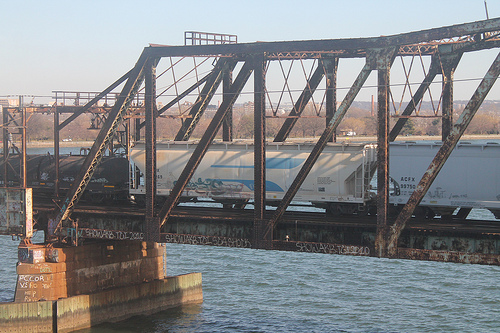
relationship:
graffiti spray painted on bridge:
[170, 218, 252, 238] [3, 13, 498, 269]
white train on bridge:
[277, 151, 377, 194] [31, 62, 498, 264]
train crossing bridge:
[0, 137, 498, 222] [30, 16, 499, 267]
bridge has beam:
[55, 13, 498, 267] [146, 43, 267, 55]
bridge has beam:
[55, 13, 498, 267] [381, 17, 498, 49]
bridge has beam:
[55, 13, 498, 267] [261, 37, 377, 54]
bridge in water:
[30, 16, 499, 267] [0, 232, 500, 330]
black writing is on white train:
[397, 172, 417, 193] [277, 151, 377, 194]